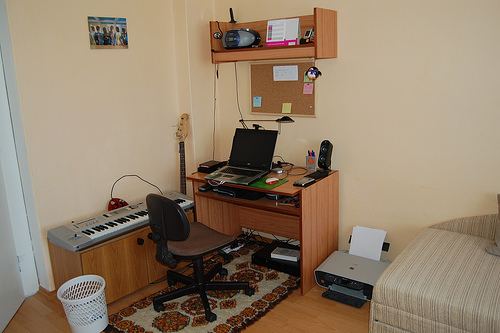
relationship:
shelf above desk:
[209, 7, 329, 63] [188, 151, 346, 289]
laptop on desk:
[207, 122, 281, 188] [188, 151, 346, 289]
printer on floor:
[318, 224, 386, 305] [13, 239, 378, 332]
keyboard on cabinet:
[43, 187, 194, 255] [35, 213, 214, 312]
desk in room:
[188, 151, 346, 289] [3, 6, 499, 333]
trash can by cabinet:
[52, 271, 120, 332] [35, 213, 214, 312]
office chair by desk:
[146, 195, 258, 322] [188, 151, 346, 289]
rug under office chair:
[115, 229, 300, 332] [146, 195, 258, 322]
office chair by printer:
[146, 195, 258, 322] [318, 224, 386, 305]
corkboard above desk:
[246, 64, 317, 122] [188, 151, 346, 289]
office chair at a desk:
[146, 195, 258, 322] [188, 151, 346, 289]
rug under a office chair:
[115, 229, 300, 332] [146, 195, 258, 322]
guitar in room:
[174, 111, 197, 198] [3, 6, 499, 333]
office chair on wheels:
[146, 195, 258, 322] [158, 270, 257, 322]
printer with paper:
[318, 224, 386, 305] [346, 229, 383, 262]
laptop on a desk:
[207, 122, 281, 188] [188, 151, 346, 289]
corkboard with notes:
[246, 64, 317, 122] [250, 63, 318, 116]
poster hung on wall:
[84, 16, 129, 54] [7, 4, 199, 232]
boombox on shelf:
[218, 28, 253, 50] [209, 7, 329, 63]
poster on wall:
[84, 16, 129, 54] [7, 4, 199, 232]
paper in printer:
[346, 229, 383, 262] [318, 224, 386, 305]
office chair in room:
[146, 195, 258, 322] [3, 6, 499, 333]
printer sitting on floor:
[318, 224, 386, 305] [13, 239, 378, 332]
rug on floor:
[115, 229, 300, 332] [13, 239, 378, 332]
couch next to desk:
[364, 218, 499, 326] [188, 151, 346, 289]